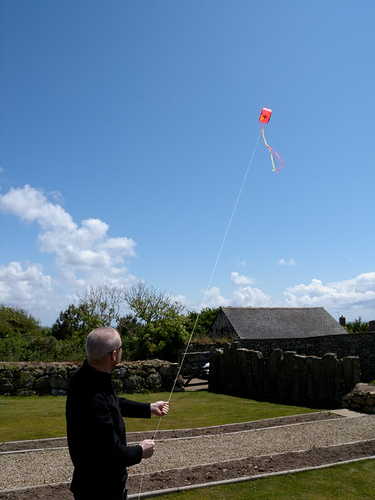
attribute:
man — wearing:
[38, 291, 209, 494]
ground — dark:
[0, 406, 374, 498]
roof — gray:
[208, 305, 347, 340]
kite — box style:
[225, 85, 300, 178]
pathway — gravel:
[0, 411, 368, 489]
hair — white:
[85, 327, 122, 366]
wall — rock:
[206, 340, 373, 412]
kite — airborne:
[260, 103, 272, 122]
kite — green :
[259, 107, 292, 172]